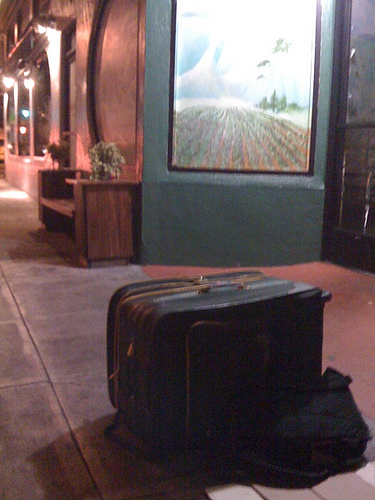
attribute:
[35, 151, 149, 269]
bench — brown, wooden, long, wood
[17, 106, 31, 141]
reflection — streetlight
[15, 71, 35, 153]
window — shining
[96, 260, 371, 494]
luggage — blue, unzipped, black, brown, square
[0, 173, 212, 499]
sidewalk — concrete, grey, gray, cement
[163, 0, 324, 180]
poster — agricultural, farm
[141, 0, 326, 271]
wall — blue, old, teal, painted, green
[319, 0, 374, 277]
door — wooden, brown, large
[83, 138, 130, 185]
plant — small, potted, green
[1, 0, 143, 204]
wall — recessed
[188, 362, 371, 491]
backpack — black, small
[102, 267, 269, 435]
trim — tan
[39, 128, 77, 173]
plant — potted, green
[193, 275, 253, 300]
handle — brown